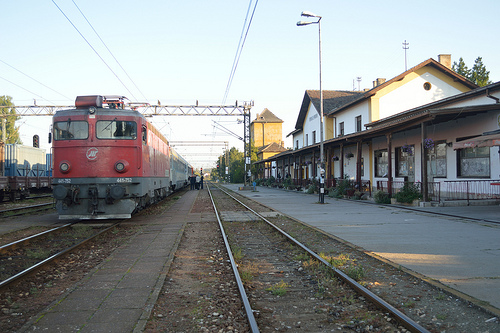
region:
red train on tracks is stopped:
[50, 96, 195, 219]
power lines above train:
[0, 1, 262, 103]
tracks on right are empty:
[203, 178, 430, 332]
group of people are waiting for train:
[177, 167, 214, 190]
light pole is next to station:
[292, 8, 334, 211]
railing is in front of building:
[330, 176, 499, 206]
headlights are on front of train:
[58, 106, 128, 178]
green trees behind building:
[450, 55, 497, 90]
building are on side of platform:
[242, 54, 498, 207]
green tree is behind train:
[0, 93, 17, 143]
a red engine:
[13, 80, 218, 240]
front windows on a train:
[42, 82, 163, 159]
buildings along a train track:
[257, 76, 497, 212]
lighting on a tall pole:
[281, 1, 362, 223]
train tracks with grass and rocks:
[193, 197, 363, 330]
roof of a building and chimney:
[381, 26, 498, 130]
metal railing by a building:
[372, 167, 497, 218]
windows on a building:
[363, 135, 497, 187]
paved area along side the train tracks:
[304, 178, 483, 305]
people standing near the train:
[166, 146, 228, 211]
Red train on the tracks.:
[45, 94, 203, 224]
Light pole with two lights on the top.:
[296, 9, 328, 203]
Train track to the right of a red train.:
[202, 178, 429, 332]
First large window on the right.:
[454, 136, 493, 181]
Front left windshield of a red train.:
[52, 119, 89, 142]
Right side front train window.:
[94, 117, 139, 142]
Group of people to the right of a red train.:
[186, 170, 206, 192]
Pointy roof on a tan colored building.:
[245, 108, 292, 179]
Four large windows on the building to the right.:
[370, 139, 492, 179]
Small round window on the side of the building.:
[421, 79, 432, 92]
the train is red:
[47, 111, 170, 169]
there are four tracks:
[12, 227, 337, 294]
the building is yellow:
[250, 102, 280, 163]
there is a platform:
[286, 188, 463, 257]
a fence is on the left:
[443, 171, 498, 206]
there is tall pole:
[308, 39, 331, 203]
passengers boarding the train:
[187, 160, 209, 200]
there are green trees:
[1, 93, 19, 154]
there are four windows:
[378, 143, 490, 180]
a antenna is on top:
[399, 38, 411, 78]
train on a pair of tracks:
[39, 88, 201, 233]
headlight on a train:
[84, 102, 99, 119]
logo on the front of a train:
[83, 142, 104, 164]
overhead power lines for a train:
[42, 0, 157, 109]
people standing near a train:
[182, 167, 209, 194]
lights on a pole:
[287, 5, 330, 45]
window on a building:
[389, 140, 419, 182]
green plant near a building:
[370, 185, 395, 212]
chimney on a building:
[432, 47, 457, 75]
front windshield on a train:
[89, 115, 141, 148]